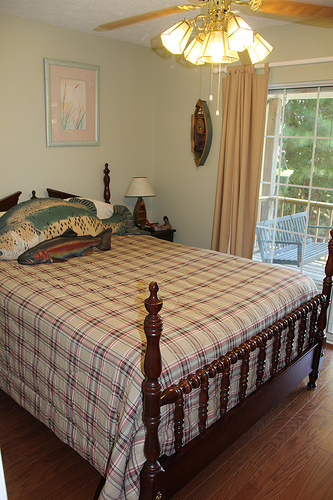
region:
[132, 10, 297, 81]
ceiling fan in the ceiling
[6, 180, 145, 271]
two fish pillows on the bed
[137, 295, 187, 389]
bed has post on each end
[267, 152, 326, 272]
hanging bench outside door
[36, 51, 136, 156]
picture hanging above the bed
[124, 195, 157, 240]
lamp is a boat shape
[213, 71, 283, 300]
curtains are open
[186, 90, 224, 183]
boat decoration on the wall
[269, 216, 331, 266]
hanging bench is blue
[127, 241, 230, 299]
bed spread is plaid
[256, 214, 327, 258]
Green hanging porch swing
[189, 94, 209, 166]
Small decorative wood boat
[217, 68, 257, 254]
Tan colored window drapery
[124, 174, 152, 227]
Canoe lamp with shade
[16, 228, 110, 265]
Stuffed plush colorful fish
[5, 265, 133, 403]
Checked design bed spread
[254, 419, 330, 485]
Distinct grain hardwood flooring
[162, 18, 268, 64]
Ceiling fan light fixture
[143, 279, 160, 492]
Dark wood bed post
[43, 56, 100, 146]
Decorative framed wall picture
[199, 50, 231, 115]
strings for the light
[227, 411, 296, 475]
dark hardwood flooring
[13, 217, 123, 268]
a fish pillow on the bed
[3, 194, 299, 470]
a plaid bed cover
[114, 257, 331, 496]
wooden bed frame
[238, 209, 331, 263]
wooden bench on the deck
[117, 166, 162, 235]
a lamp on the nightstand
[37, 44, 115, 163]
pink picture on the wall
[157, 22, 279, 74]
lights on the fan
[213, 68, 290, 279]
curtain for the window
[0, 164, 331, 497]
King sized bed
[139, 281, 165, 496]
left bed hole on the foot portion of the bed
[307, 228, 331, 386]
Right bed pole on the foot portion of the bed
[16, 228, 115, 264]
Fake fish on the bed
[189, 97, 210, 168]
Fake fish hooked onto the wall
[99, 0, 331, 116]
Beige fan on top of the bed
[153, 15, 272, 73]
Couple of lights below the fan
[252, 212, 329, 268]
bench that's outside of the house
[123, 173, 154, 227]
Small lamp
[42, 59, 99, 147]
Small picture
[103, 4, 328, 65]
a ceiling fan and light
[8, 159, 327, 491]
a four poster bed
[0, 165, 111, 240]
a wooden head board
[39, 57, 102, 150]
a framed art print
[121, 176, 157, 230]
a table lamp and shade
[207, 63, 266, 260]
a beige curtain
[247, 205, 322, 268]
an outdoor slat bench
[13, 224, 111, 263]
a plush fish pillow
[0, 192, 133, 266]
a plush fish pillow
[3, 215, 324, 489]
a plaid bed spread